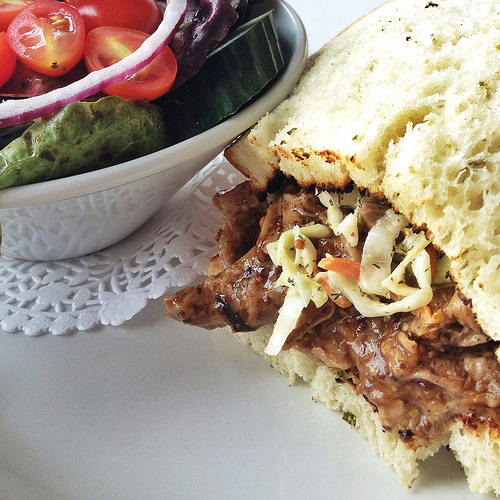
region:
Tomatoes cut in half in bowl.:
[28, 7, 125, 101]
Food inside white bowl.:
[21, 174, 146, 334]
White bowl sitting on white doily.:
[11, 254, 153, 314]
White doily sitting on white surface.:
[60, 280, 126, 378]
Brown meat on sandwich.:
[248, 245, 381, 433]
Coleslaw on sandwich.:
[279, 227, 453, 340]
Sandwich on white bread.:
[396, 189, 499, 310]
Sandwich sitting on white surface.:
[216, 272, 367, 451]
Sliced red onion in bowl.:
[65, 52, 177, 156]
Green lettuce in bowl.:
[23, 81, 121, 163]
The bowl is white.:
[6, 4, 311, 265]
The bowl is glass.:
[5, 5, 317, 270]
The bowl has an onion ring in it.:
[0, 6, 197, 118]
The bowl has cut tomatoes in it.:
[0, 7, 184, 112]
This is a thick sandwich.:
[202, 27, 497, 468]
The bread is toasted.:
[225, 7, 487, 280]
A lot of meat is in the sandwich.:
[193, 180, 493, 467]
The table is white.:
[11, 345, 263, 494]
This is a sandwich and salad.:
[11, 3, 496, 408]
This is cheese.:
[248, 178, 472, 380]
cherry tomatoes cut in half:
[6, 3, 108, 82]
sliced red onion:
[0, 8, 179, 105]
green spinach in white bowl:
[8, 106, 187, 213]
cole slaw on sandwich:
[277, 163, 453, 345]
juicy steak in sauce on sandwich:
[217, 194, 444, 434]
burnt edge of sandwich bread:
[259, 126, 419, 241]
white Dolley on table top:
[15, 220, 248, 435]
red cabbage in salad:
[172, 1, 234, 74]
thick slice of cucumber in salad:
[177, 16, 319, 135]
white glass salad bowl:
[3, 84, 325, 291]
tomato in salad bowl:
[20, 5, 81, 75]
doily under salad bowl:
[0, 186, 220, 356]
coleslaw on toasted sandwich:
[250, 225, 426, 325]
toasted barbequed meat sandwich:
[215, 55, 470, 466]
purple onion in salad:
[0, 5, 187, 113]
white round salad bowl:
[0, 0, 280, 281]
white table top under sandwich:
[20, 320, 440, 490]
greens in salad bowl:
[0, 1, 263, 206]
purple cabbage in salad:
[171, 5, 281, 88]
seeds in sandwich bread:
[455, 158, 487, 185]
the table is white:
[0, 2, 484, 472]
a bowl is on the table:
[2, 5, 353, 275]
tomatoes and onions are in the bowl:
[1, 2, 172, 99]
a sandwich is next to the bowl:
[224, 17, 485, 491]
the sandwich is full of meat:
[205, 134, 490, 484]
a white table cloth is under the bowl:
[4, 85, 369, 373]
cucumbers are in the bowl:
[165, 14, 319, 116]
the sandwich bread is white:
[248, 18, 489, 233]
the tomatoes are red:
[0, 7, 145, 69]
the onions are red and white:
[0, 4, 242, 185]